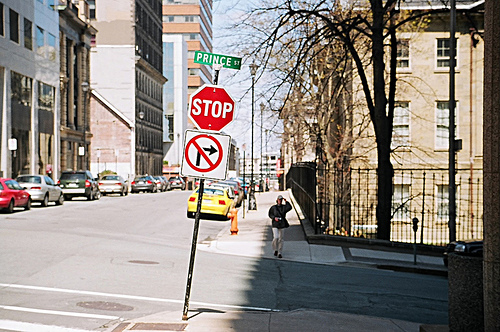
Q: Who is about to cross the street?
A: A person.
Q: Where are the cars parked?
A: By the sidewalk.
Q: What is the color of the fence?
A: Black.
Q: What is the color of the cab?
A: Yellow.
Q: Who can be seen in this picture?
A: A pedestrian.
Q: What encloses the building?
A: A black, metal fence.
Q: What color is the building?
A: Tan.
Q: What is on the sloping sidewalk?
A: A parking meter.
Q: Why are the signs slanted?
A: They're on a hill.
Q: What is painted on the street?
A: White crosswalk lines.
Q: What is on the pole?
A: Road signs.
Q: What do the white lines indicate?
A: A cross walk.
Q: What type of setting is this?
A: An urban area.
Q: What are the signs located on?
A: A metal pole.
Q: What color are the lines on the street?
A: White.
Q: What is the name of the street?
A: Prince.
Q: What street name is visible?
A: Prince street.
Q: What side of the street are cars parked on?
A: Both sides.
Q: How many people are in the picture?
A: One.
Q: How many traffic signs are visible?
A: Two.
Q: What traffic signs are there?
A: Stop and no right turn.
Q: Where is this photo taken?
A: In a city.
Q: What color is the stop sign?
A: Red.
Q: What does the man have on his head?
A: A hat.